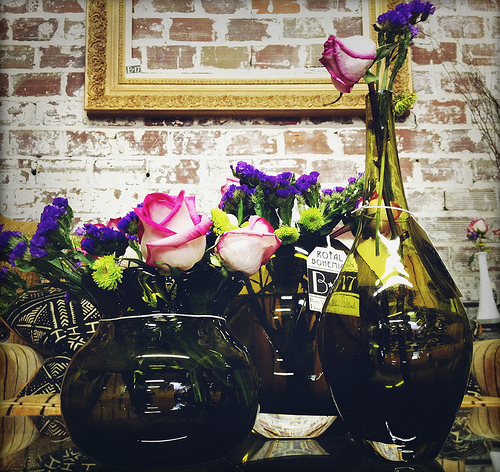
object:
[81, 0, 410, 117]
frame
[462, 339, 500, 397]
couch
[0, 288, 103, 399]
pillow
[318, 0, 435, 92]
flowers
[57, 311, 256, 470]
vase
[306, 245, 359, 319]
tag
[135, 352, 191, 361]
reflection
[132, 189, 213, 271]
rose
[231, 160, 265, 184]
flower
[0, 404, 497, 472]
table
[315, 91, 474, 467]
vase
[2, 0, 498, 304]
wall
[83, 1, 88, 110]
edge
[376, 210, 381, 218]
part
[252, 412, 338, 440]
bulb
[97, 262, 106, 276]
part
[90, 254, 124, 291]
flower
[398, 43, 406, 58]
part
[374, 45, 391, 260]
stem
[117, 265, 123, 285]
edge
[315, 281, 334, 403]
side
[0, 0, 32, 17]
part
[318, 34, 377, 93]
rose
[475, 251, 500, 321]
vase